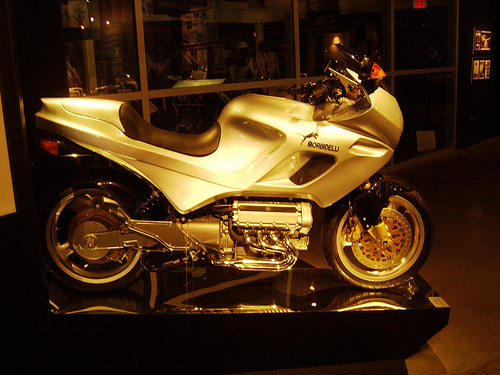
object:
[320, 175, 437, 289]
tire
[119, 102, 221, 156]
seat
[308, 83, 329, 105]
handlebar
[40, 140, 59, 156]
light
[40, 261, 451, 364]
platform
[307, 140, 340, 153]
logo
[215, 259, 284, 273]
pipe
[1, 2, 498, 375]
building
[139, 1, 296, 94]
window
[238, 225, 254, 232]
cyclinder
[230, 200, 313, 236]
engine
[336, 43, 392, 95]
window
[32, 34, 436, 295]
bike